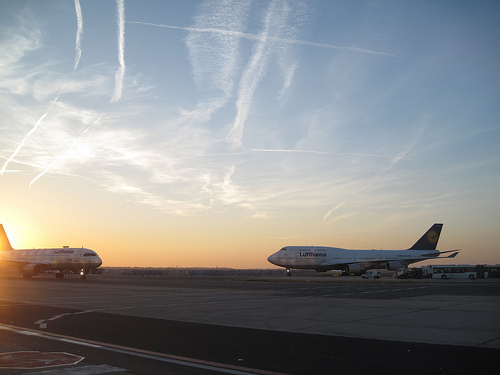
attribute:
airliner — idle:
[267, 221, 462, 277]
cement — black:
[1, 273, 498, 358]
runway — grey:
[2, 263, 493, 373]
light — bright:
[9, 225, 51, 250]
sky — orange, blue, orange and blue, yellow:
[3, 12, 499, 260]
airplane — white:
[2, 225, 104, 279]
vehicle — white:
[350, 262, 387, 283]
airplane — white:
[269, 195, 436, 287]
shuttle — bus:
[399, 266, 481, 281]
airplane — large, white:
[265, 219, 466, 295]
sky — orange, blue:
[0, 0, 497, 217]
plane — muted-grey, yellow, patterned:
[248, 205, 443, 309]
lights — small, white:
[47, 266, 299, 302]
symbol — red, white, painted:
[0, 349, 85, 370]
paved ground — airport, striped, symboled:
[0, 274, 499, 372]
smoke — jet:
[1, 0, 424, 229]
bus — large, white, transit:
[424, 263, 479, 279]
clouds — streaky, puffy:
[48, 54, 283, 222]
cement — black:
[2, 299, 478, 372]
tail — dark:
[409, 220, 444, 251]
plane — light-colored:
[266, 220, 461, 282]